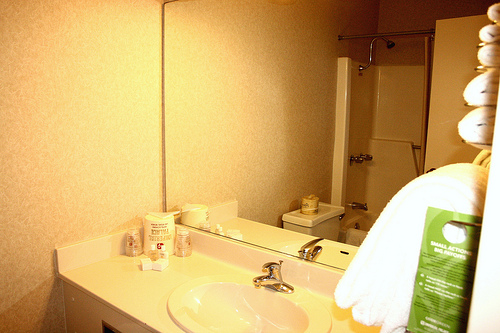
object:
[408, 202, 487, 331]
door tag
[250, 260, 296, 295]
fixtures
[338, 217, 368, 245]
area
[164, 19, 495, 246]
reflection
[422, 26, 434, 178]
shower curtain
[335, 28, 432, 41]
pole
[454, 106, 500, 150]
towels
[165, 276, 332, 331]
sink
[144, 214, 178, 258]
candle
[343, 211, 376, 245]
tub reflection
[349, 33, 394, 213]
shower reflection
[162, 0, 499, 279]
mirror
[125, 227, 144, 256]
cup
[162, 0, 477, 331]
wall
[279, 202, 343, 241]
toilet tank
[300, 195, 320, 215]
tissue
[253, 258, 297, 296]
faucet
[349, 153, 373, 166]
shower handle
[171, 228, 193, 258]
toiletry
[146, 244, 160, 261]
toiletry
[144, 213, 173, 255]
toiletry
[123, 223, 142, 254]
toiletry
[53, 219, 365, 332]
counter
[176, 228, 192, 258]
cups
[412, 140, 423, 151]
towel bar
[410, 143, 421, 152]
end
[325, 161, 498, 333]
towels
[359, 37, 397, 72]
shower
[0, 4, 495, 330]
bath room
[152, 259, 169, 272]
small soaps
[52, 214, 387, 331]
vanity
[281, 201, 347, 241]
toilet